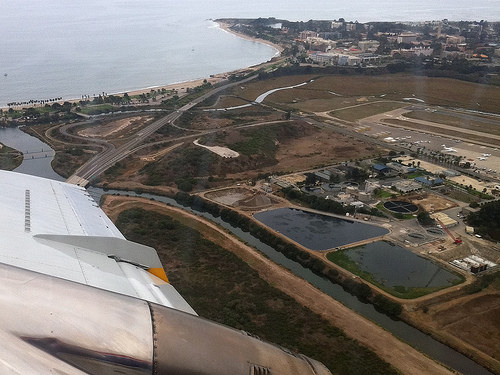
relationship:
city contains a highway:
[215, 13, 497, 76] [62, 143, 139, 185]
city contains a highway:
[215, 13, 497, 76] [116, 139, 145, 158]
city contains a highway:
[215, 13, 497, 76] [142, 112, 180, 133]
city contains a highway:
[215, 13, 497, 76] [175, 104, 202, 113]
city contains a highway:
[215, 13, 497, 76] [214, 74, 246, 92]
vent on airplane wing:
[242, 362, 268, 373] [0, 166, 333, 373]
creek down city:
[1, 125, 493, 373] [112, 179, 498, 361]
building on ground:
[415, 168, 448, 190] [142, 21, 495, 359]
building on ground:
[390, 173, 422, 193] [142, 21, 495, 359]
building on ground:
[368, 157, 393, 172] [142, 21, 495, 359]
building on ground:
[348, 160, 375, 175] [142, 21, 495, 359]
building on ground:
[309, 167, 334, 183] [142, 21, 495, 359]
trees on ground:
[407, 140, 492, 219] [287, 107, 477, 216]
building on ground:
[369, 164, 393, 174] [213, 15, 498, 373]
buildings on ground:
[382, 28, 472, 51] [0, 108, 222, 167]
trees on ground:
[246, 122, 277, 162] [280, 134, 352, 179]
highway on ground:
[65, 74, 260, 187] [60, 94, 320, 205]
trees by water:
[117, 205, 430, 373] [168, 198, 363, 333]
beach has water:
[8, 60, 273, 127] [5, 121, 491, 369]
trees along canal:
[115, 191, 430, 375] [124, 194, 483, 373]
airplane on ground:
[472, 150, 490, 166] [327, 99, 499, 182]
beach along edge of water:
[0, 18, 285, 127] [1, 3, 289, 117]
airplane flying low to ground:
[0, 169, 334, 374] [11, 8, 496, 171]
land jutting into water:
[3, 15, 496, 373] [3, 3, 499, 103]